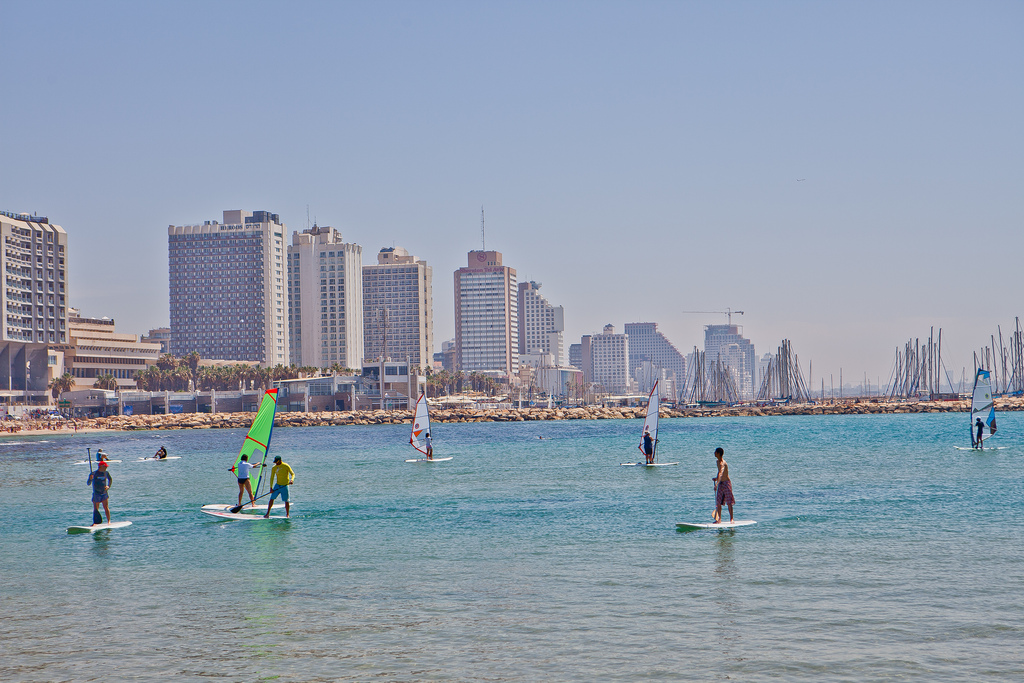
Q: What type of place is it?
A: It is a city.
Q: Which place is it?
A: It is a city.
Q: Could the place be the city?
A: Yes, it is the city.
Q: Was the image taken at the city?
A: Yes, it was taken in the city.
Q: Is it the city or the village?
A: It is the city.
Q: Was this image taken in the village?
A: No, the picture was taken in the city.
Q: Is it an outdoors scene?
A: Yes, it is outdoors.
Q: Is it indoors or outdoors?
A: It is outdoors.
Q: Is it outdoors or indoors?
A: It is outdoors.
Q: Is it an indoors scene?
A: No, it is outdoors.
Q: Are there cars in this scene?
A: No, there are no cars.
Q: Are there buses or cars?
A: No, there are no cars or buses.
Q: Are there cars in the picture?
A: No, there are no cars.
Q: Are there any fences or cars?
A: No, there are no cars or fences.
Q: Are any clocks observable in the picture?
A: No, there are no clocks.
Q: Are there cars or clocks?
A: No, there are no clocks or cars.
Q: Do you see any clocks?
A: No, there are no clocks.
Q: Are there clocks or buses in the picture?
A: No, there are no clocks or buses.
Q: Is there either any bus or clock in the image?
A: No, there are no clocks or buses.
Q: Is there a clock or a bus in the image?
A: No, there are no clocks or buses.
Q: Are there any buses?
A: No, there are no buses.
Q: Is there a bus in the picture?
A: No, there are no buses.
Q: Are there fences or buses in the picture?
A: No, there are no buses or fences.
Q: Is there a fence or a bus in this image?
A: No, there are no buses or fences.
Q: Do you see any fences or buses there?
A: No, there are no buses or fences.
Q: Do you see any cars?
A: No, there are no cars.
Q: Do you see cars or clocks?
A: No, there are no cars or clocks.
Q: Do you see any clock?
A: No, there are no clocks.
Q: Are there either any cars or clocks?
A: No, there are no clocks or cars.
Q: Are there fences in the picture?
A: No, there are no fences.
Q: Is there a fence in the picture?
A: No, there are no fences.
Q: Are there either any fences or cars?
A: No, there are no fences or cars.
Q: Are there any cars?
A: No, there are no cars.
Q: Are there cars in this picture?
A: No, there are no cars.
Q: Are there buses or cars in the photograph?
A: No, there are no cars or buses.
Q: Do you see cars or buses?
A: No, there are no cars or buses.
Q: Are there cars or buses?
A: No, there are no cars or buses.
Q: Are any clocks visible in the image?
A: No, there are no clocks.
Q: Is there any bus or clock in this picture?
A: No, there are no clocks or buses.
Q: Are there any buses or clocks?
A: No, there are no clocks or buses.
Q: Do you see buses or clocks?
A: No, there are no clocks or buses.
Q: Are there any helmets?
A: No, there are no helmets.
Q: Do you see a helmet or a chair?
A: No, there are no helmets or chairs.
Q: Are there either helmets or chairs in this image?
A: No, there are no helmets or chairs.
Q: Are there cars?
A: No, there are no cars.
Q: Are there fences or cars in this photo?
A: No, there are no cars or fences.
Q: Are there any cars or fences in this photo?
A: No, there are no cars or fences.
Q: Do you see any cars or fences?
A: No, there are no cars or fences.